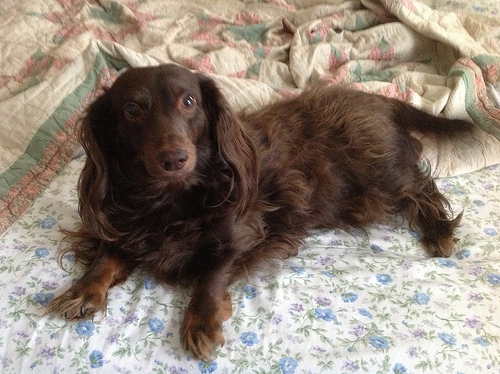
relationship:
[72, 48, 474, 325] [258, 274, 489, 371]
dog on sheet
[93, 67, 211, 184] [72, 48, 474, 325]
face of dog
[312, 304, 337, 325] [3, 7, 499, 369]
flower on bed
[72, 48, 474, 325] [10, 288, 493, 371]
dog lying on bed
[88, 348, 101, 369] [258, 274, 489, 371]
flower on sheet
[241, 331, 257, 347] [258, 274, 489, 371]
flower on sheet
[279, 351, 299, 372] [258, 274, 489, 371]
flower on sheet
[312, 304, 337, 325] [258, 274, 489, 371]
flower on sheet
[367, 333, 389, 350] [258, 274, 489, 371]
flower on sheet